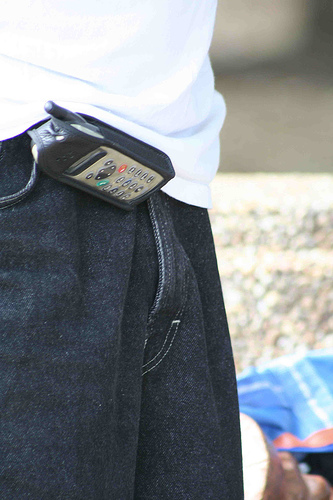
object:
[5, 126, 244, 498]
pants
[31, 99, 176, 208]
phone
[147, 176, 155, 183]
buttons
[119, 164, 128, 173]
button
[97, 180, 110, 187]
button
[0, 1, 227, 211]
shirt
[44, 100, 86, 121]
antenna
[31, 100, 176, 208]
case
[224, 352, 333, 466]
something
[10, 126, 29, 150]
belt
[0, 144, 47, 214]
pocket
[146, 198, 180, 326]
fly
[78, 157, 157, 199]
keypad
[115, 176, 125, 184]
button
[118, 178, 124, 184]
letters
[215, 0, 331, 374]
background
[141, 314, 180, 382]
seams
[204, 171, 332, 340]
sand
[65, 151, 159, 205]
front